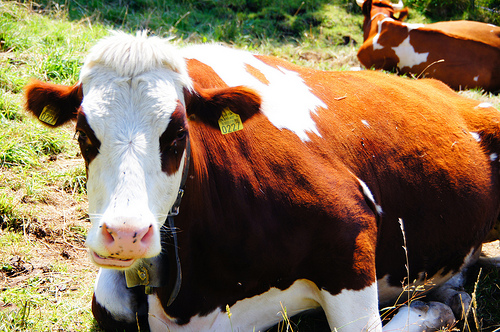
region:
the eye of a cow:
[153, 125, 192, 160]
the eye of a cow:
[70, 118, 100, 155]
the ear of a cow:
[188, 82, 260, 132]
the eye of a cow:
[22, 80, 80, 129]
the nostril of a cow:
[133, 224, 152, 243]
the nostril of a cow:
[98, 220, 118, 245]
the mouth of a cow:
[84, 240, 149, 278]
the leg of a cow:
[302, 210, 440, 327]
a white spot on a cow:
[226, 48, 331, 143]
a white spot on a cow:
[386, 32, 436, 72]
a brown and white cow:
[11, 21, 492, 330]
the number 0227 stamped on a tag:
[213, 104, 246, 141]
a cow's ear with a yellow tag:
[171, 73, 266, 141]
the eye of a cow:
[160, 131, 197, 162]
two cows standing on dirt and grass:
[18, 0, 498, 330]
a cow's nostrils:
[85, 203, 167, 258]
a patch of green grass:
[108, 3, 360, 35]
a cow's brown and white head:
[16, 41, 278, 281]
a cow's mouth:
[87, 239, 162, 273]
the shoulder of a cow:
[258, 135, 423, 329]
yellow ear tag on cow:
[176, 71, 273, 167]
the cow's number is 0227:
[189, 73, 271, 154]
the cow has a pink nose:
[58, 182, 180, 280]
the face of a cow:
[11, 55, 273, 290]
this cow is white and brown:
[26, 51, 278, 285]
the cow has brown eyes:
[21, 53, 283, 297]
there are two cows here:
[6, 5, 498, 242]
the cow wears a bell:
[13, 17, 282, 309]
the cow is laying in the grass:
[8, 11, 493, 323]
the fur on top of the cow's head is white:
[13, 12, 282, 304]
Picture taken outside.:
[18, 10, 466, 263]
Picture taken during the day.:
[39, 39, 351, 321]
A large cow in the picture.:
[8, 30, 424, 293]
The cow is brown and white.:
[52, 19, 376, 203]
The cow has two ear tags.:
[16, 60, 274, 217]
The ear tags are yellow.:
[35, 64, 272, 196]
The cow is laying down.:
[29, 30, 384, 330]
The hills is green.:
[26, 19, 326, 58]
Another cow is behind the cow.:
[360, 14, 494, 89]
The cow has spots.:
[62, 27, 349, 162]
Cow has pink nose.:
[119, 205, 145, 253]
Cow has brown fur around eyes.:
[85, 135, 226, 225]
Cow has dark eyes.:
[76, 111, 211, 210]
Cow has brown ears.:
[13, 70, 322, 157]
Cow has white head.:
[107, 89, 164, 291]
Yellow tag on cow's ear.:
[198, 84, 287, 192]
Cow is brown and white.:
[86, 102, 421, 328]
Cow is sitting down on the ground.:
[10, 189, 252, 329]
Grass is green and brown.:
[23, 183, 95, 317]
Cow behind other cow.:
[352, 4, 495, 144]